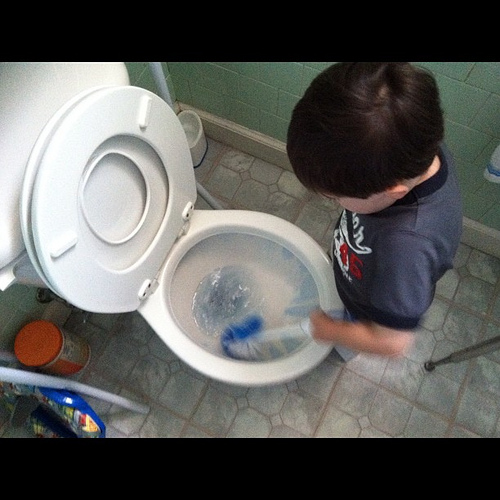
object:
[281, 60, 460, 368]
person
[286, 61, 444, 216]
head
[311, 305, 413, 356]
arm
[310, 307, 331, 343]
hand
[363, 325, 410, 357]
elbow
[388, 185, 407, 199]
ear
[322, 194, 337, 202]
eyebrow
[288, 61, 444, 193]
hair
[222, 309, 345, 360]
toilet brush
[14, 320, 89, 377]
wet wipes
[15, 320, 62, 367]
lid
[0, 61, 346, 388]
toilet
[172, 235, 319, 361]
toilet bowl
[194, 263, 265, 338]
water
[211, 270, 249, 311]
soap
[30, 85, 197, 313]
toilet seat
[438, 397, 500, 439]
tile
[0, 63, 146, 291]
tank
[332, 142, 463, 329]
shirt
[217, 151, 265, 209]
tiles